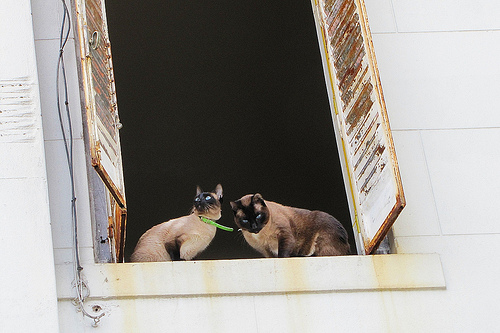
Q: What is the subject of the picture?
A: Two cats.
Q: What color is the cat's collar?
A: Green.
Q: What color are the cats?
A: Brown.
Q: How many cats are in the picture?
A: Two.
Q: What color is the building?
A: White.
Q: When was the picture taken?
A: During the day.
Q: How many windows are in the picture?
A: One.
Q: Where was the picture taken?
A: Outside a window.